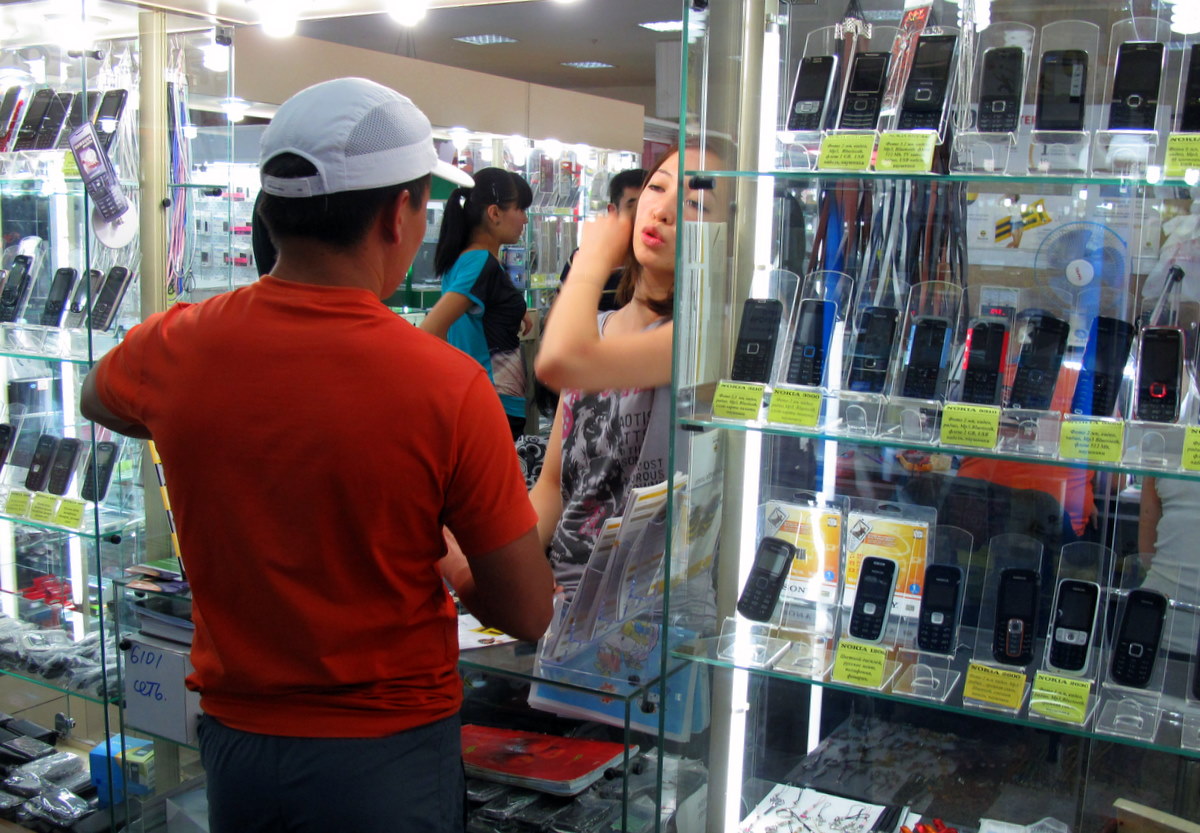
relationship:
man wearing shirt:
[81, 74, 554, 833] [88, 259, 533, 730]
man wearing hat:
[81, 74, 554, 833] [249, 69, 473, 204]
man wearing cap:
[81, 74, 554, 833] [258, 78, 474, 198]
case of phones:
[648, 15, 1162, 811] [749, 19, 1156, 756]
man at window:
[81, 74, 554, 833] [171, 4, 674, 700]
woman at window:
[522, 145, 747, 665] [227, 10, 678, 679]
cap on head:
[264, 69, 475, 197] [249, 165, 430, 284]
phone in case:
[727, 290, 788, 377] [648, 15, 1162, 811]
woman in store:
[414, 165, 536, 447] [11, 14, 1184, 816]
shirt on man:
[88, 259, 533, 730] [81, 74, 554, 833]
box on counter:
[118, 630, 203, 745] [114, 547, 655, 819]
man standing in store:
[66, 60, 594, 828] [11, 14, 1184, 816]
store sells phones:
[11, 14, 1184, 816] [775, 29, 1193, 829]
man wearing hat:
[66, 60, 594, 828] [254, 73, 487, 219]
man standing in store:
[81, 74, 554, 833] [11, 14, 1184, 816]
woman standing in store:
[414, 165, 536, 447] [11, 14, 1184, 816]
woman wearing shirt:
[414, 165, 536, 447] [433, 245, 531, 386]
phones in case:
[712, 500, 1198, 715] [670, 1, 1193, 827]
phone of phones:
[729, 299, 783, 386] [734, 291, 1198, 428]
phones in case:
[734, 291, 1198, 428] [670, 1, 1193, 827]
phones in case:
[786, 23, 1196, 138] [670, 1, 1193, 827]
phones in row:
[786, 23, 1196, 138] [758, 14, 1174, 171]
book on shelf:
[457, 705, 640, 811] [467, 697, 711, 825]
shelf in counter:
[467, 697, 711, 825] [430, 631, 704, 827]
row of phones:
[781, 35, 1200, 135] [727, 20, 1196, 709]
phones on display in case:
[727, 20, 1196, 709] [670, 1, 1193, 827]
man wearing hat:
[81, 74, 554, 833] [241, 73, 515, 223]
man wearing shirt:
[81, 74, 554, 833] [110, 276, 535, 775]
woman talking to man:
[533, 147, 746, 694] [81, 74, 554, 833]